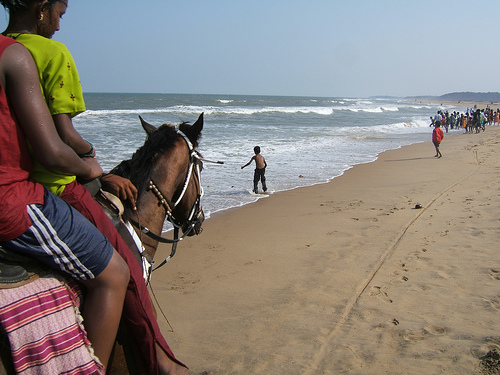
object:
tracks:
[304, 180, 467, 373]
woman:
[1, 4, 98, 113]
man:
[2, 42, 128, 277]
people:
[439, 102, 457, 123]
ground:
[378, 197, 399, 220]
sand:
[376, 210, 491, 365]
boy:
[0, 36, 132, 373]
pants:
[52, 174, 196, 374]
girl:
[2, 1, 204, 371]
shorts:
[3, 186, 114, 281]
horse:
[0, 106, 240, 373]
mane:
[86, 117, 208, 213]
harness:
[160, 121, 206, 241]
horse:
[0, 110, 204, 373]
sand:
[109, 96, 499, 373]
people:
[0, 6, 138, 369]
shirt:
[1, 29, 85, 119]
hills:
[363, 89, 499, 105]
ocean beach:
[141, 98, 498, 372]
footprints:
[372, 259, 422, 297]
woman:
[426, 121, 450, 158]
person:
[2, 31, 129, 372]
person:
[2, 1, 97, 154]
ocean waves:
[71, 92, 498, 234]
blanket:
[1, 297, 75, 338]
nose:
[192, 212, 208, 233]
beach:
[3, 100, 498, 374]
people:
[430, 120, 444, 157]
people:
[473, 109, 481, 132]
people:
[460, 112, 468, 134]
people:
[495, 107, 499, 125]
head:
[140, 113, 212, 240]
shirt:
[0, 36, 44, 239]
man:
[0, 2, 130, 368]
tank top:
[0, 33, 47, 245]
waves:
[77, 100, 447, 142]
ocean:
[74, 93, 479, 238]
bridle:
[152, 122, 207, 233]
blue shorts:
[2, 187, 120, 294]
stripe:
[0, 287, 79, 327]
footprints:
[368, 170, 463, 358]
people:
[428, 106, 496, 136]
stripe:
[28, 207, 90, 291]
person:
[1, 9, 134, 372]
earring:
[32, 6, 52, 26]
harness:
[107, 165, 199, 289]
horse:
[63, 86, 252, 335]